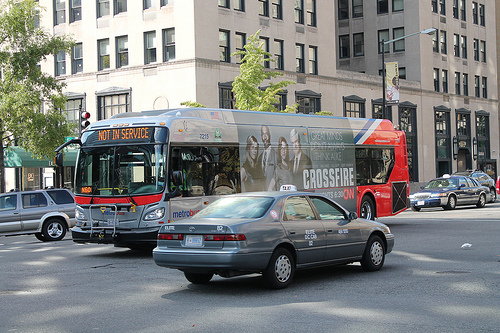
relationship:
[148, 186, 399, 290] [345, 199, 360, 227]
car has mirror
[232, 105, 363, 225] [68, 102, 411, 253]
ad on bus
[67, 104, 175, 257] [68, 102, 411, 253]
front of bus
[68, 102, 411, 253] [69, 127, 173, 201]
bus has windshield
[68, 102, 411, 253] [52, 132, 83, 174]
bus has mirror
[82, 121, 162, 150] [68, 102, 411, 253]
sign on bus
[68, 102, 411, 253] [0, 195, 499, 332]
bus on street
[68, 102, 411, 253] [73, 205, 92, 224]
bus has headlight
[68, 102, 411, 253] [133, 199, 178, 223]
bus has headlight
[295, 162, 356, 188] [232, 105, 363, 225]
letters on ad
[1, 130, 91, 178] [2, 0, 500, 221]
awning on building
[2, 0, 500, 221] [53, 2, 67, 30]
building has window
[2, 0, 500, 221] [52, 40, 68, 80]
building has window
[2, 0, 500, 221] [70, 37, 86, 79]
building has window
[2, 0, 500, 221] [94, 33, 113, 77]
building has window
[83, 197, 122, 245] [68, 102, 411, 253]
rack on bus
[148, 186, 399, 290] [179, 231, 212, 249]
car has license plate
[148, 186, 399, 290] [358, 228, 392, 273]
car has tire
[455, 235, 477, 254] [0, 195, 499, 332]
paper on street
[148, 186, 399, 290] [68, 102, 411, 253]
taxi beside bus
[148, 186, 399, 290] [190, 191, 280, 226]
car has windshield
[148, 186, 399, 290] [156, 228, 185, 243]
car has brake light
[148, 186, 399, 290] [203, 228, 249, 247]
car has brake light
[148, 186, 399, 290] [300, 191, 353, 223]
car has window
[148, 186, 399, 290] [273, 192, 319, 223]
car has window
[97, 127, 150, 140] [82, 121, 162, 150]
letters on sign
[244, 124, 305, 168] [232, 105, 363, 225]
people in ad